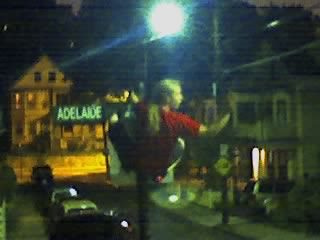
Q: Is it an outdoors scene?
A: Yes, it is outdoors.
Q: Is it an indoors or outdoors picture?
A: It is outdoors.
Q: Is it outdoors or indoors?
A: It is outdoors.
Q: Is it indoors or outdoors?
A: It is outdoors.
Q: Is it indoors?
A: No, it is outdoors.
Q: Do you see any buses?
A: No, there are no buses.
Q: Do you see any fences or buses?
A: No, there are no buses or fences.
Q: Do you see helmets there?
A: No, there are no helmets.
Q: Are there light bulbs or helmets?
A: No, there are no helmets or light bulbs.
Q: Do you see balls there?
A: No, there are no balls.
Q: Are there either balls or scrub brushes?
A: No, there are no balls or scrub brushes.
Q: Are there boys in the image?
A: No, there are no boys.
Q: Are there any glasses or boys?
A: No, there are no boys or glasses.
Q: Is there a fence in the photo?
A: No, there are no fences.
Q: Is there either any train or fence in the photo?
A: No, there are no fences or trains.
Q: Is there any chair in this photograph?
A: No, there are no chairs.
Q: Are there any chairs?
A: No, there are no chairs.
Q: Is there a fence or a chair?
A: No, there are no chairs or fences.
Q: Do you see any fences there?
A: No, there are no fences.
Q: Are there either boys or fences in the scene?
A: No, there are no fences or boys.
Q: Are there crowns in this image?
A: No, there are no crowns.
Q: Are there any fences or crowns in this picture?
A: No, there are no crowns or fences.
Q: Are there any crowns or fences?
A: No, there are no crowns or fences.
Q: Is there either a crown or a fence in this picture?
A: No, there are no crowns or fences.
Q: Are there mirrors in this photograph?
A: No, there are no mirrors.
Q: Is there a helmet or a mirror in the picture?
A: No, there are no mirrors or helmets.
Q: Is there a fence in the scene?
A: No, there are no fences.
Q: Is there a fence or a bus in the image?
A: No, there are no fences or buses.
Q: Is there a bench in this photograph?
A: No, there are no benches.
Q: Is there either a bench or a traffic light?
A: No, there are no benches or traffic lights.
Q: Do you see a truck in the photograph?
A: No, there are no trucks.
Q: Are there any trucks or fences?
A: No, there are no trucks or fences.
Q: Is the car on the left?
A: Yes, the car is on the left of the image.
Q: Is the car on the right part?
A: No, the car is on the left of the image.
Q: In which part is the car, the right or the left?
A: The car is on the left of the image.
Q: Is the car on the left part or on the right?
A: The car is on the left of the image.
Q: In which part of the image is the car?
A: The car is on the left of the image.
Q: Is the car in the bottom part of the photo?
A: Yes, the car is in the bottom of the image.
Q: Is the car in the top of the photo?
A: No, the car is in the bottom of the image.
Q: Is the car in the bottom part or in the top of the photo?
A: The car is in the bottom of the image.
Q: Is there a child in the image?
A: No, there are no children.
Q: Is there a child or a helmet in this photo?
A: No, there are no children or helmets.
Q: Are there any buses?
A: No, there are no buses.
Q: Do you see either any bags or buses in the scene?
A: No, there are no buses or bags.